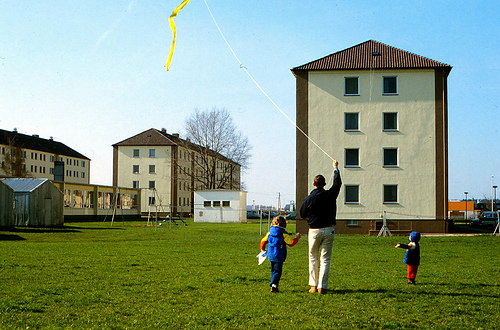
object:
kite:
[164, 0, 192, 70]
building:
[289, 37, 453, 234]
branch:
[205, 123, 211, 137]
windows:
[384, 78, 394, 94]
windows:
[347, 76, 357, 97]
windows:
[385, 112, 400, 129]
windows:
[346, 112, 358, 131]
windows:
[383, 150, 395, 166]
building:
[112, 128, 244, 218]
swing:
[103, 186, 168, 226]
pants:
[406, 263, 420, 283]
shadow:
[323, 286, 497, 298]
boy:
[395, 231, 421, 284]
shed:
[1, 176, 66, 231]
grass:
[4, 217, 498, 328]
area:
[4, 230, 498, 322]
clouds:
[56, 8, 178, 26]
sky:
[3, 1, 490, 215]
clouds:
[22, 38, 39, 53]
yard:
[4, 221, 314, 326]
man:
[298, 164, 345, 295]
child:
[258, 215, 301, 292]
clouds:
[38, 69, 107, 118]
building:
[0, 127, 141, 221]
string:
[204, 1, 335, 160]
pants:
[269, 261, 282, 290]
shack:
[195, 189, 245, 223]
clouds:
[42, 27, 76, 43]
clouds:
[256, 36, 286, 58]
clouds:
[185, 55, 222, 93]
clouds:
[50, 16, 102, 51]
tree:
[181, 107, 253, 190]